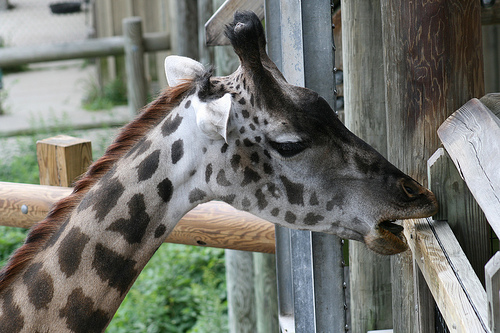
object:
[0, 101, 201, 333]
neck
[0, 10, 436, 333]
giraffe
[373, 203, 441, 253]
mouth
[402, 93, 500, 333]
fence